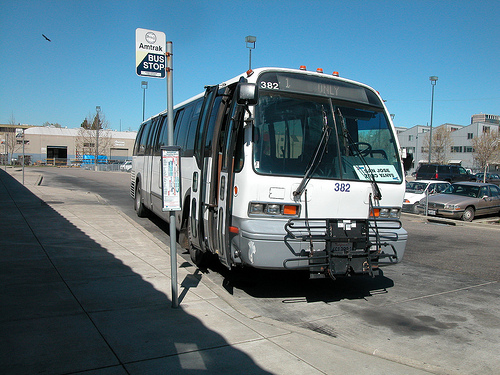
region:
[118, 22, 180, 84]
black and white sign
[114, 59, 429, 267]
white transit bus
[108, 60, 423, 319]
The bus is white.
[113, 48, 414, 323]
The bus has no driver.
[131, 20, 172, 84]
The sign is blue and white.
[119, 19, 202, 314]
The sign is attached to a post.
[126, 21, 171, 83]
The sign is rectangular.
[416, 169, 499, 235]
The car is parked.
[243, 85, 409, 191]
The windshield of the bus is tinted.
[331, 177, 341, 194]
The number is black.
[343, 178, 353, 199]
The number is black.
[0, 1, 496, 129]
The sky is blue and clear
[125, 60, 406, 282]
A long white bus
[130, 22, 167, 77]
A blue and white sign with "BUS STOP" on it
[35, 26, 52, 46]
A bird is flying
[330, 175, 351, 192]
Number 382 on the bus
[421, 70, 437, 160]
A tall street lamp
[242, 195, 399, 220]
Headlights on front of a bus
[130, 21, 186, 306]
Gray pole holding up sign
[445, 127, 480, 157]
Windows on a building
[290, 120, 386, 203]
Two black windshield wipers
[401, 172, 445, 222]
a white car parked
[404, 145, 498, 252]
cars parked in a parking lot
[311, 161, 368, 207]
the number 382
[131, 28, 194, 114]
a amtrak sign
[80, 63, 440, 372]
a white bus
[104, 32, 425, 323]
a white bus parked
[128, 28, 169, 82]
black and white sign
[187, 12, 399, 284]
white transit bus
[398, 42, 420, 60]
white clouds in blue sky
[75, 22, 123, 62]
white clouds in blue sky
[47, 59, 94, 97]
white clouds in blue sky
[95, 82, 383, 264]
bus